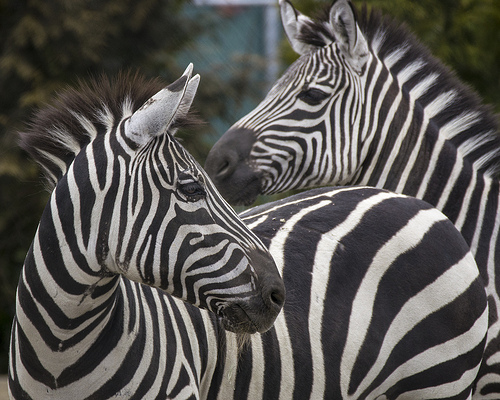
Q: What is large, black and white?
A: A zebra.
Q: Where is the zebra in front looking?
A: Right.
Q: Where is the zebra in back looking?
A: Left.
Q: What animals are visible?
A: Zebras.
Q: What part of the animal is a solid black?
A: Nose.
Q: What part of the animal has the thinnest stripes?
A: Head.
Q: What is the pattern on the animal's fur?
A: Stripes.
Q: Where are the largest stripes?
A: Rear end of the animal.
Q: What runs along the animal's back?
A: Mane.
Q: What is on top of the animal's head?
A: Ears.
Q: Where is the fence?
A: Between trees.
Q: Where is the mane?
A: On zebra.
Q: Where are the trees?
A: Behind zebras.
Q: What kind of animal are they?
A: Zebras.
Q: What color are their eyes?
A: Black.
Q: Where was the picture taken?
A: In a zoo.